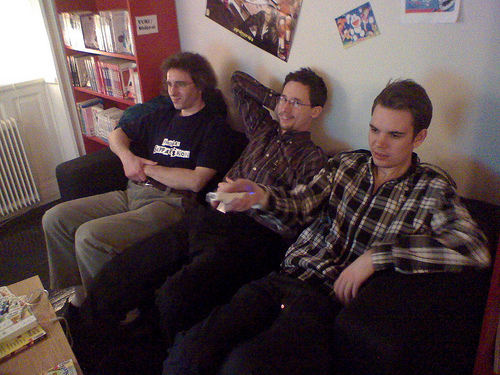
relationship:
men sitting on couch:
[42, 53, 493, 374] [55, 138, 499, 368]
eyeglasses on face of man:
[277, 94, 311, 110] [93, 72, 329, 349]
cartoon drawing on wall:
[332, 2, 383, 53] [174, 0, 500, 201]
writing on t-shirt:
[151, 136, 190, 160] [117, 110, 233, 188]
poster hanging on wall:
[204, 2, 303, 61] [174, 0, 500, 201]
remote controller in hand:
[206, 191, 246, 205] [216, 175, 267, 215]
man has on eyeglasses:
[93, 72, 329, 349] [277, 94, 311, 110]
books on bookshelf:
[60, 8, 140, 140] [56, 2, 181, 157]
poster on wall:
[204, 2, 303, 61] [174, 0, 500, 201]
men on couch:
[42, 53, 493, 374] [55, 138, 499, 368]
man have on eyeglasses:
[93, 72, 329, 349] [277, 94, 311, 110]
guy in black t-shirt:
[43, 53, 225, 323] [117, 110, 233, 188]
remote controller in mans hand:
[206, 191, 246, 205] [216, 175, 267, 215]